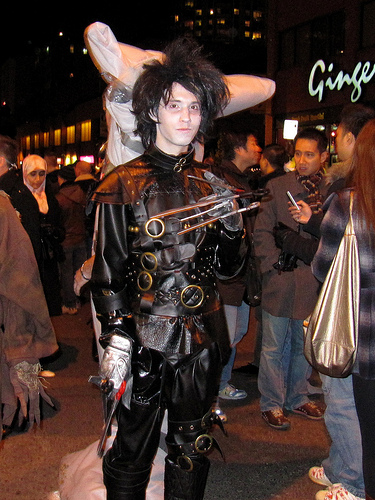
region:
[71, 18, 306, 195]
the man has dark hair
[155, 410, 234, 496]
the man is wearing buckles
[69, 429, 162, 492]
a white bag is behind the man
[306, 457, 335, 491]
the man has red and white shoes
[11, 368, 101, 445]
the man has long nails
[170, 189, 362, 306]
the man is wearing scissors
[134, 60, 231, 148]
head of a person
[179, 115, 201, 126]
nose of a person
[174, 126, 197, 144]
mouth of a person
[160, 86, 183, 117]
eye of a person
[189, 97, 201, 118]
eye of a person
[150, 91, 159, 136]
ear of a person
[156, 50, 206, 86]
hair of a person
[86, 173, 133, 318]
arm of a person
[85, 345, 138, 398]
hand of a person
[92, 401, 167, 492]
leg of a person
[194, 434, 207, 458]
GOLD BUCKLE ON BOOT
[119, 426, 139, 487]
BLACK LEATHER BOOTS ON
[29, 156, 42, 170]
WOMAN WEARING A HEAD SCARF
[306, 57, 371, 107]
SIGN ON THE BUILDING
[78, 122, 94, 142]
WINDOWS ON THE BUILDING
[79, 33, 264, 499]
a man in an Edward Scissorhands costume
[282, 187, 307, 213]
a man holding a phone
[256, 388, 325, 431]
a man with red shoes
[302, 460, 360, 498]
a man with white and red shoes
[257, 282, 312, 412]
a man wearing jeans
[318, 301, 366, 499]
a man wearing jeans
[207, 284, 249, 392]
a man wearing jeans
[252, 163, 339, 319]
a man wearing a grey coat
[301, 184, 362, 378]
a woman with a gold purse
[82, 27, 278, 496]
A man dressed up as Edward Scissorhands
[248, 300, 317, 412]
A pair of blue jeans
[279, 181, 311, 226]
A cell phone in a hand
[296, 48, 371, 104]
"Ginge" written on a building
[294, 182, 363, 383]
A bag is bronze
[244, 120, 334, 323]
Man wearing a long gray coat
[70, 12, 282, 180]
Person wearing a white costume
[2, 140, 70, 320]
Woman has on a long black coat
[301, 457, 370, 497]
A pair of white shoes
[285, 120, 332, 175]
A guy has black hair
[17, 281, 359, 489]
A concrete floor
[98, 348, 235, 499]
The black leather pants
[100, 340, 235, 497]
A pair of leather pants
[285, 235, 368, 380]
A gold bag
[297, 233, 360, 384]
The gold bag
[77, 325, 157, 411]
A silver glove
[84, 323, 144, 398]
The silver glove on the man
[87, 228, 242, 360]
The black jacket on the man